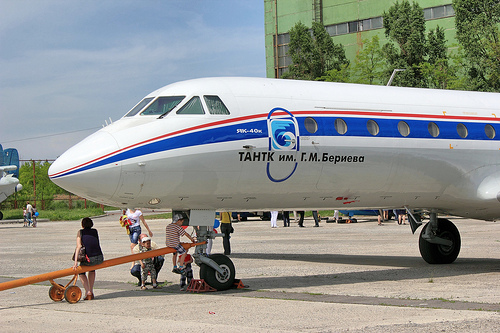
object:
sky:
[0, 0, 267, 167]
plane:
[46, 76, 499, 291]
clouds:
[0, 0, 266, 170]